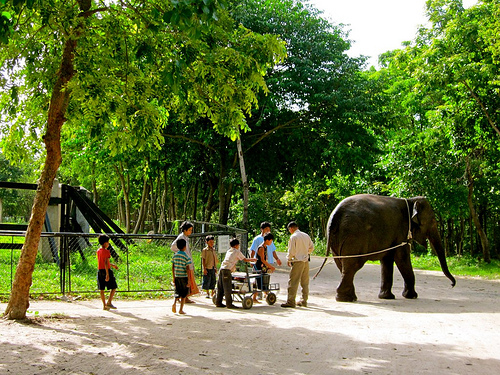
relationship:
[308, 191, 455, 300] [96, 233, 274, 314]
elephant pulling boy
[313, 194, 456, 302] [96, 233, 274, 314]
elephant entertaining boy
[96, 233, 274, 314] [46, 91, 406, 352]
boy playing in park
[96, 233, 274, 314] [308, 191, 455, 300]
boy playing with elephant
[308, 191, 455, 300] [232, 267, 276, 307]
elephant pulling wagon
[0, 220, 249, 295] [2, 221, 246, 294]
fence going around area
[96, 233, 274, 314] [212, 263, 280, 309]
boy pushing cart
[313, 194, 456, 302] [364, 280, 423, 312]
elephant on ground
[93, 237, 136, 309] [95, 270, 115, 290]
boy wearing shorts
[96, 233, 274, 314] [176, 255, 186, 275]
boy wearing shirt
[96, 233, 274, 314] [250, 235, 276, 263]
boy wearing blue shirt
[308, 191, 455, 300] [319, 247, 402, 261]
elephant held by rope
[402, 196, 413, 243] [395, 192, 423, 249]
rope around neck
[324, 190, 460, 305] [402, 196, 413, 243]
elephant has rope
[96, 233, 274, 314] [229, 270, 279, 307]
boy pushing cart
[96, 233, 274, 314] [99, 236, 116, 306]
boy pushing boy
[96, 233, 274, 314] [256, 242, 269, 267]
boy wearing top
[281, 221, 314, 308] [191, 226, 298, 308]
handler talking to kids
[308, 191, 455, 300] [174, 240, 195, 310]
elephant in front of boy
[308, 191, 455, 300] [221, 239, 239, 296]
elephant in front of boy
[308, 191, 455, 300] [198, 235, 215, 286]
elephant in front of boy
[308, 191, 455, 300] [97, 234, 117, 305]
elephant in front of boy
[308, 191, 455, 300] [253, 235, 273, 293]
elephant in front of boy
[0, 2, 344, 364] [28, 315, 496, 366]
tree on road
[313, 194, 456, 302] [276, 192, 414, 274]
elephant with handler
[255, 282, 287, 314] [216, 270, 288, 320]
wheel on wagon